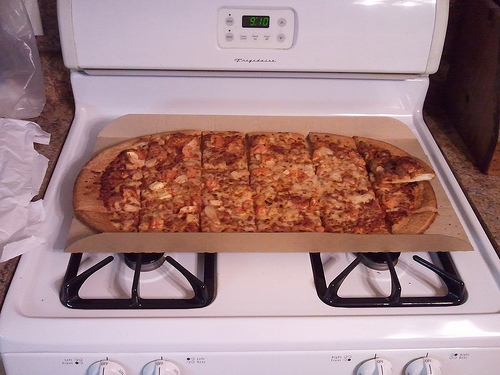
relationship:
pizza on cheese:
[352, 136, 435, 182] [73, 130, 438, 234]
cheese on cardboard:
[73, 130, 438, 234] [61, 114, 475, 253]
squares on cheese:
[150, 130, 248, 183] [73, 130, 438, 234]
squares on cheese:
[245, 138, 388, 225] [73, 130, 438, 234]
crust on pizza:
[404, 145, 441, 240] [52, 94, 482, 252]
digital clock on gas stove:
[242, 13, 271, 28] [0, 0, 500, 375]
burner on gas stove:
[308, 252, 467, 308] [6, 0, 499, 373]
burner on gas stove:
[58, 252, 218, 310] [6, 0, 499, 373]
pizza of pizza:
[352, 136, 435, 182] [356, 130, 444, 190]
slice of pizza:
[358, 133, 403, 160] [58, 105, 445, 254]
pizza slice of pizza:
[249, 164, 326, 232] [106, 137, 445, 237]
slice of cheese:
[245, 126, 315, 178] [73, 130, 438, 234]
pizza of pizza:
[200, 169, 257, 233] [200, 182, 255, 230]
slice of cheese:
[199, 128, 253, 173] [73, 130, 438, 234]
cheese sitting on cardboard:
[73, 130, 438, 234] [63, 105, 480, 267]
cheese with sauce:
[73, 130, 438, 234] [93, 131, 413, 236]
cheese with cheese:
[73, 130, 438, 234] [94, 128, 418, 228]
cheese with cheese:
[73, 130, 438, 234] [73, 130, 438, 234]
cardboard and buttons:
[64, 113, 474, 253] [219, 7, 294, 49]